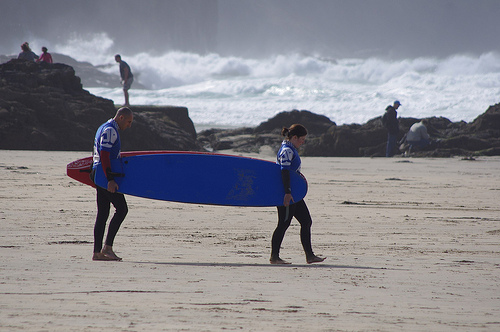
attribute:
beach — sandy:
[308, 158, 498, 330]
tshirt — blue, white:
[92, 116, 118, 166]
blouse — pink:
[40, 50, 50, 60]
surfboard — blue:
[43, 136, 335, 233]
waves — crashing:
[221, 121, 314, 156]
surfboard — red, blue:
[91, 152, 307, 207]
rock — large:
[11, 26, 237, 197]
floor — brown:
[2, 147, 498, 330]